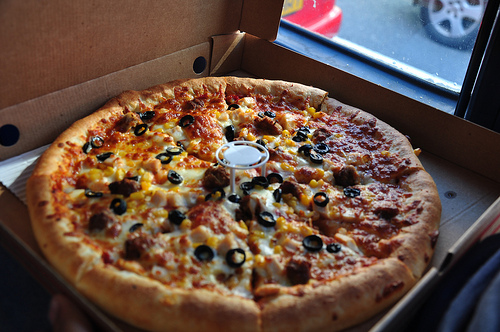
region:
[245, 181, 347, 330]
Slice of pizza with crust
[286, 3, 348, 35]
red car parked outside of window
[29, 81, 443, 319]
olive cheese pizza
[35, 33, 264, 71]
cardboard box that pizza is in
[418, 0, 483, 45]
wheel outside of window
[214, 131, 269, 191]
topper for pizza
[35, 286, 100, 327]
thumb of a person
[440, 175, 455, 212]
grease spot on cardbox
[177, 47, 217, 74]
hole in brown card box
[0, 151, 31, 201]
napkin underneath pizza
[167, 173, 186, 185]
BLACK OLIVES ARE ON TOP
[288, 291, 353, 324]
CRUST OF THE PIZZA IS THICK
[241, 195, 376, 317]
PIZZA IS CUT IN SLICES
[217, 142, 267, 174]
WHITE STAND IS IN THE MIDDLE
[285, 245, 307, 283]
MEAT IS ON THE TOP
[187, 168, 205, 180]
WHITE CHEESE IS MELTED ON TOP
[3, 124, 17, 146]
HOLES ARE IN THE BOX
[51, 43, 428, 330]
PIZZA IS IN THE BOX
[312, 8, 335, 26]
RED CAR OUTSIDE THE WINDOW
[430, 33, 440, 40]
TIRE IS BLACK ON THE CAR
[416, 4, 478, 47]
the tire of the car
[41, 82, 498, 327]
the pizza in the box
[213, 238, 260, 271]
olives on the piza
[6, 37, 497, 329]
the box is cardboard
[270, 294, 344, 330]
the crust of the pizza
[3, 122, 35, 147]
the hole in the box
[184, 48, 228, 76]
the hole in the box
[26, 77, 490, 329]
the box is open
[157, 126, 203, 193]
the cheese on the pizza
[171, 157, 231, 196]
the cheese is melted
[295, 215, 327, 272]
Black olive on top of pizza.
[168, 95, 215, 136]
Red sauce on top of pizza.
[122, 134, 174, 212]
Yellow pepper on top of pizza.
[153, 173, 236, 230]
White cheese melted on top of pizza.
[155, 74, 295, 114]
Golden brown crust on pizza.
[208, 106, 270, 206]
Plastic white object in center of pizza.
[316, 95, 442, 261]
Pizza cut in to slices.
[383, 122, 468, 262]
Pizza sitting in pizza box.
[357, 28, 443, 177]
Pizza near a window.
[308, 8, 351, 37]
Red car near window.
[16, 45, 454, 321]
a pizza in a box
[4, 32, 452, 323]
a thick pizza in a box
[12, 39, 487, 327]
a cheesy pizza in a box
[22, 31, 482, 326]
a pizza with cheese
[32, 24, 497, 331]
a pizza with red sauce on pizza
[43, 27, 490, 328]
a pizza with red sauce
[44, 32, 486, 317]
pizza in a brown box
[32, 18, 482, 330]
a pizza cut into slices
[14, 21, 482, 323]
pizza with black olives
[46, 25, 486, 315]
a pizza with cheese and black olives